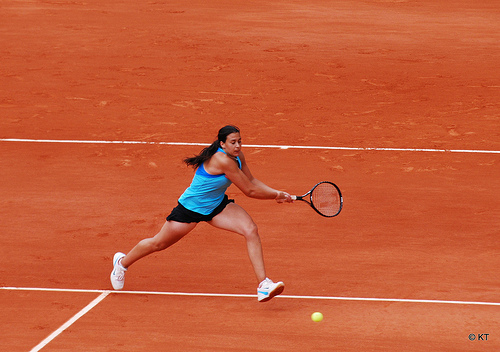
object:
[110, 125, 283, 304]
woman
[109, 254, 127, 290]
shoes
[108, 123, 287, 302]
player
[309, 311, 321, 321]
tennis ball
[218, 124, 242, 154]
head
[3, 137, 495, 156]
white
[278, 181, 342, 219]
tennis rakett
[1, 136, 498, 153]
line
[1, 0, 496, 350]
tennis court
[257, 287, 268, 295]
design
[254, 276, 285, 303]
shoe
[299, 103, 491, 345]
court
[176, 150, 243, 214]
shirt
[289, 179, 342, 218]
racket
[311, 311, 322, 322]
ball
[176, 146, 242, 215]
skirt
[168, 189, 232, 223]
shorts